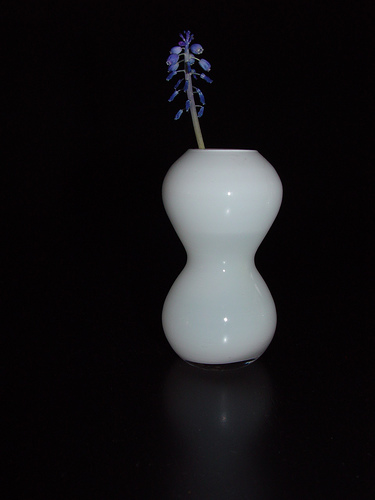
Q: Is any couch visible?
A: No, there are no couches.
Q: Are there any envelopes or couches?
A: No, there are no couches or envelopes.